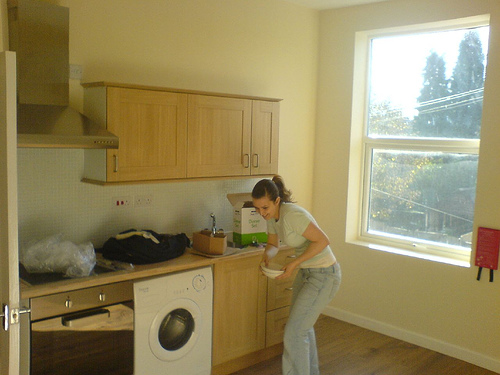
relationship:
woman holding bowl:
[253, 175, 341, 374] [261, 264, 285, 279]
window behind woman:
[359, 25, 490, 261] [253, 175, 341, 374]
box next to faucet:
[229, 193, 267, 245] [211, 212, 217, 237]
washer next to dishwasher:
[134, 266, 212, 374] [29, 279, 134, 374]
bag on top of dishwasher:
[23, 234, 96, 278] [29, 279, 134, 374]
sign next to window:
[475, 228, 499, 280] [359, 25, 490, 261]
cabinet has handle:
[81, 82, 187, 185] [114, 155, 118, 172]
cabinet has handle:
[188, 90, 251, 181] [246, 155, 249, 167]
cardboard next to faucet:
[193, 230, 228, 254] [211, 212, 217, 237]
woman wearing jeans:
[253, 175, 341, 374] [287, 264, 341, 374]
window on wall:
[359, 25, 490, 261] [317, 0, 499, 373]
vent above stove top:
[7, 0, 118, 148] [19, 260, 112, 285]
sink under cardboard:
[190, 236, 251, 251] [193, 230, 228, 254]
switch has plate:
[118, 201, 128, 204] [111, 196, 131, 207]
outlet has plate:
[136, 197, 150, 204] [133, 195, 151, 206]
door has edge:
[0, 51, 21, 374] [7, 50, 17, 373]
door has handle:
[0, 51, 21, 374] [0, 306, 30, 330]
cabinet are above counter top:
[188, 90, 251, 181] [20, 230, 287, 300]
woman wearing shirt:
[253, 175, 341, 374] [266, 202, 335, 266]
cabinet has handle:
[249, 96, 282, 177] [255, 154, 259, 167]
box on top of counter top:
[229, 193, 267, 245] [20, 230, 287, 300]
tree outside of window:
[414, 52, 450, 135] [359, 25, 490, 261]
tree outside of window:
[450, 32, 484, 138] [359, 25, 490, 261]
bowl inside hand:
[261, 264, 285, 279] [275, 266, 290, 280]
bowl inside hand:
[261, 264, 285, 279] [259, 254, 266, 276]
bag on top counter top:
[23, 234, 96, 278] [20, 230, 287, 300]